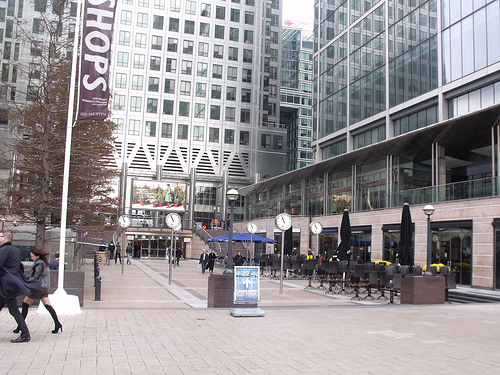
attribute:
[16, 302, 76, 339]
boots — high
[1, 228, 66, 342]
people — walking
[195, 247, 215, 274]
people — walking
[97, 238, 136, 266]
people — walking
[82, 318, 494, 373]
floor — tiled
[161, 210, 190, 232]
clock — black, white, most right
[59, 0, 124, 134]
banner — round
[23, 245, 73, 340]
lady — walking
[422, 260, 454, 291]
flower — yellow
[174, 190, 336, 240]
clocks — five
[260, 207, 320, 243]
clock — white, black, most left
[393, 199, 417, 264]
umbrella — closest, black, closed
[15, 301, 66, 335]
boots — knee high